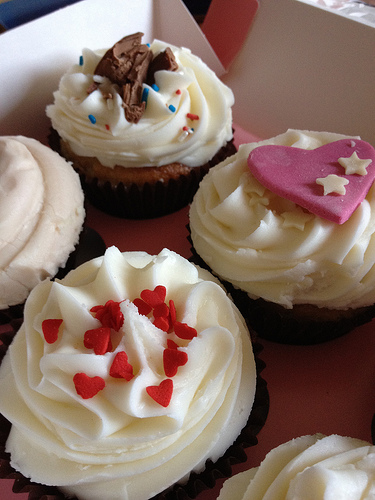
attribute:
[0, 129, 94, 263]
frosting — white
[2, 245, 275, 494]
cupcake — chocolate, decorated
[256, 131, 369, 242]
heart — pink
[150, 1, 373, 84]
box — pink, white, cardboard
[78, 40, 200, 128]
sprinkles — blue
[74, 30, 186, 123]
bits — chocolate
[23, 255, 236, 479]
icing — swirled, white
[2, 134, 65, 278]
icing — pink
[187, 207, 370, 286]
icing — pink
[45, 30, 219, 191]
cupcake — chocolate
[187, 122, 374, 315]
cupcake — chocolate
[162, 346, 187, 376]
heart — red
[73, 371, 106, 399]
heart — red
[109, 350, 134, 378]
heart — red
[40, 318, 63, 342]
heart — red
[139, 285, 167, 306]
heart — red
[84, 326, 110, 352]
topping — red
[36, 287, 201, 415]
topping — red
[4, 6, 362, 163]
box — white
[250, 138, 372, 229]
heart — pink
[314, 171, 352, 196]
star — white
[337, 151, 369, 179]
star — white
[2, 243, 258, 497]
frosting — white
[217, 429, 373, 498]
frosting — white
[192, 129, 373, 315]
frosting — white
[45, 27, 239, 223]
cupcake — chocolate